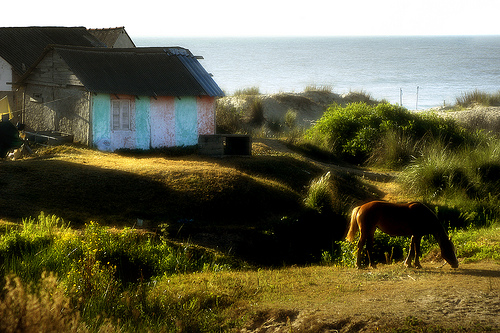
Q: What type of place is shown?
A: It is a field.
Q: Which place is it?
A: It is a field.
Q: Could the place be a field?
A: Yes, it is a field.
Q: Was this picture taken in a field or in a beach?
A: It was taken at a field.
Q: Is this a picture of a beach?
A: No, the picture is showing a field.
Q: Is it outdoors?
A: Yes, it is outdoors.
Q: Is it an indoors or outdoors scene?
A: It is outdoors.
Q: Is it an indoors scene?
A: No, it is outdoors.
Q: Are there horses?
A: Yes, there is a horse.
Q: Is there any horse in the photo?
A: Yes, there is a horse.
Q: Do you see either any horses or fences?
A: Yes, there is a horse.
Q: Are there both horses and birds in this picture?
A: No, there is a horse but no birds.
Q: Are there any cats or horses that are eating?
A: Yes, the horse is eating.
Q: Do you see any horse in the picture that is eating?
A: Yes, there is a horse that is eating.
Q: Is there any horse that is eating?
A: Yes, there is a horse that is eating.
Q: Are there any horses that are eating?
A: Yes, there is a horse that is eating.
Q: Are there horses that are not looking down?
A: Yes, there is a horse that is eating.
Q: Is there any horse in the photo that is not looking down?
A: Yes, there is a horse that is eating.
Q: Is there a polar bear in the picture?
A: No, there are no polar bears.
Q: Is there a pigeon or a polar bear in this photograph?
A: No, there are no polar bears or pigeons.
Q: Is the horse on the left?
A: No, the horse is on the right of the image.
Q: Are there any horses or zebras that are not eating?
A: No, there is a horse but it is eating.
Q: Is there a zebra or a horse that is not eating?
A: No, there is a horse but it is eating.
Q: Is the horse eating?
A: Yes, the horse is eating.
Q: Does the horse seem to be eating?
A: Yes, the horse is eating.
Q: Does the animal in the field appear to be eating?
A: Yes, the horse is eating.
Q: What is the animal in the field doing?
A: The horse is eating.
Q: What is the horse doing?
A: The horse is eating.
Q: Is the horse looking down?
A: No, the horse is eating.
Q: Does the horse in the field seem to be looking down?
A: No, the horse is eating.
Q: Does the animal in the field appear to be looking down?
A: No, the horse is eating.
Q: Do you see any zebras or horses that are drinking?
A: No, there is a horse but it is eating.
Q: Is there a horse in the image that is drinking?
A: No, there is a horse but it is eating.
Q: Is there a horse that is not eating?
A: No, there is a horse but it is eating.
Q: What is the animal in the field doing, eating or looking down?
A: The horse is eating.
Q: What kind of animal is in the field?
A: The animal is a horse.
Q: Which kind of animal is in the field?
A: The animal is a horse.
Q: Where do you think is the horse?
A: The horse is in the field.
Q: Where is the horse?
A: The horse is in the field.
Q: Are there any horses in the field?
A: Yes, there is a horse in the field.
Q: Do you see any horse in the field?
A: Yes, there is a horse in the field.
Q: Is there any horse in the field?
A: Yes, there is a horse in the field.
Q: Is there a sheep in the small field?
A: No, there is a horse in the field.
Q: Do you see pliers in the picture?
A: No, there are no pliers.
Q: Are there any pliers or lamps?
A: No, there are no pliers or lamps.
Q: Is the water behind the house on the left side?
A: Yes, the water is behind the house.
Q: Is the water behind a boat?
A: No, the water is behind the house.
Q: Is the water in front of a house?
A: No, the water is behind a house.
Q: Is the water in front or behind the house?
A: The water is behind the house.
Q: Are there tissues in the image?
A: No, there are no tissues.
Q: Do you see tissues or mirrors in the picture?
A: No, there are no tissues or mirrors.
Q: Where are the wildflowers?
A: The wildflowers are on the field.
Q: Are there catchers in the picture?
A: No, there are no catchers.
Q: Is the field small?
A: Yes, the field is small.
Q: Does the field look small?
A: Yes, the field is small.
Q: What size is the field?
A: The field is small.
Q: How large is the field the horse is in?
A: The field is small.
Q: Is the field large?
A: No, the field is small.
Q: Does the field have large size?
A: No, the field is small.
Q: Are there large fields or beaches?
A: No, there is a field but it is small.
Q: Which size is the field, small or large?
A: The field is small.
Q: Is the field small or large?
A: The field is small.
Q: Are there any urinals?
A: No, there are no urinals.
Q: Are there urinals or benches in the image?
A: No, there are no urinals or benches.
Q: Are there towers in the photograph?
A: No, there are no towers.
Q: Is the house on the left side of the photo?
A: Yes, the house is on the left of the image.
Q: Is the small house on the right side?
A: No, the house is on the left of the image.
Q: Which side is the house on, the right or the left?
A: The house is on the left of the image.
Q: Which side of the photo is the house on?
A: The house is on the left of the image.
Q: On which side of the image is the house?
A: The house is on the left of the image.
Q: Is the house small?
A: Yes, the house is small.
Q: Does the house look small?
A: Yes, the house is small.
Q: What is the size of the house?
A: The house is small.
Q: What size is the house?
A: The house is small.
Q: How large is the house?
A: The house is small.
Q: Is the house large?
A: No, the house is small.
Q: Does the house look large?
A: No, the house is small.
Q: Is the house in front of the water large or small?
A: The house is small.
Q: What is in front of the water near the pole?
A: The house is in front of the water.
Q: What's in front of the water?
A: The house is in front of the water.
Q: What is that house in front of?
A: The house is in front of the water.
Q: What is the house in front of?
A: The house is in front of the water.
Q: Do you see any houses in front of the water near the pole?
A: Yes, there is a house in front of the water.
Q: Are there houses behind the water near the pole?
A: No, the house is in front of the water.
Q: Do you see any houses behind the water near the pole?
A: No, the house is in front of the water.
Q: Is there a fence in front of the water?
A: No, there is a house in front of the water.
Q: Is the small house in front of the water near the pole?
A: Yes, the house is in front of the water.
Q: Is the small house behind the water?
A: No, the house is in front of the water.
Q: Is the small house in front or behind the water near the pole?
A: The house is in front of the water.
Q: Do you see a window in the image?
A: Yes, there is a window.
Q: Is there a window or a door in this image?
A: Yes, there is a window.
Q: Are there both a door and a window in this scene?
A: No, there is a window but no doors.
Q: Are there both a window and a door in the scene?
A: No, there is a window but no doors.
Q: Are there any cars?
A: No, there are no cars.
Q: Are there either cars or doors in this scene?
A: No, there are no cars or doors.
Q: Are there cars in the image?
A: No, there are no cars.